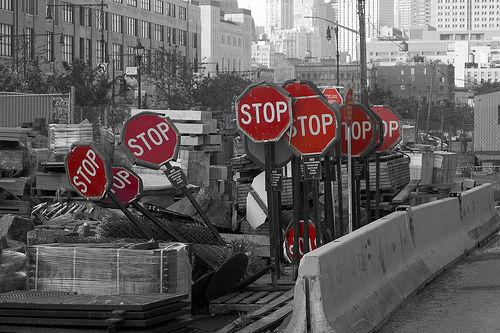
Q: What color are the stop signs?
A: Red.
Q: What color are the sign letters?
A: White.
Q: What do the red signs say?
A: Stop.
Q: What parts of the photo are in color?
A: Stop signs.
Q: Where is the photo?
A: City.